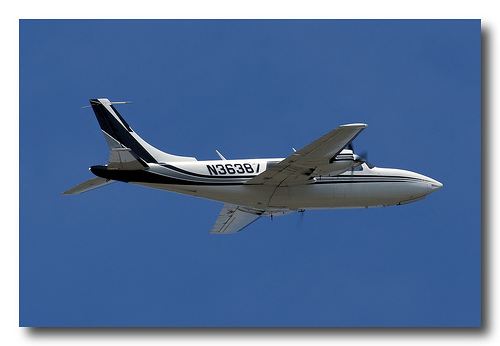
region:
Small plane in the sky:
[69, 80, 427, 255]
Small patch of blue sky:
[39, 266, 118, 342]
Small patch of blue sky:
[113, 261, 146, 298]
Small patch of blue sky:
[139, 255, 189, 312]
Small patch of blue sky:
[176, 250, 215, 300]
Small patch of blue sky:
[222, 246, 264, 290]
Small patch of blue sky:
[258, 258, 305, 315]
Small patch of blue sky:
[300, 266, 343, 316]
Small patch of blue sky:
[336, 268, 382, 305]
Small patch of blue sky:
[395, 243, 438, 302]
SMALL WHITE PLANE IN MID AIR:
[74, 84, 496, 264]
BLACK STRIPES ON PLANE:
[205, 173, 432, 187]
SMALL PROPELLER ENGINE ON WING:
[288, 145, 363, 173]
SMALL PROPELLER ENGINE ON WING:
[234, 202, 311, 222]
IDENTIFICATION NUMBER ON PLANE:
[187, 141, 272, 184]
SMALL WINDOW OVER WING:
[257, 153, 289, 166]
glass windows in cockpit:
[340, 142, 390, 183]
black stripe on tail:
[76, 78, 175, 195]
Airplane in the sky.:
[51, 85, 446, 247]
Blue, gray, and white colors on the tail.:
[85, 90, 190, 160]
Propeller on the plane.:
[350, 135, 375, 170]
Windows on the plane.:
[345, 155, 375, 175]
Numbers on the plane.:
[200, 160, 255, 175]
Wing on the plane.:
[250, 110, 365, 180]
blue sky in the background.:
[15, 20, 475, 320]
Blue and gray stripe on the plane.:
[140, 155, 425, 195]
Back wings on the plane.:
[39, 139, 155, 209]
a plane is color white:
[53, 90, 450, 244]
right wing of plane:
[258, 112, 374, 188]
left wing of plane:
[210, 200, 260, 235]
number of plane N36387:
[200, 150, 265, 177]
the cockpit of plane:
[402, 161, 447, 198]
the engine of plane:
[333, 141, 378, 181]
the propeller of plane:
[349, 141, 376, 176]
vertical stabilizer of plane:
[86, 87, 176, 162]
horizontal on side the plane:
[60, 173, 111, 203]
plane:
[74, 81, 452, 236]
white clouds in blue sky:
[277, 253, 332, 293]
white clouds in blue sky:
[357, 256, 458, 323]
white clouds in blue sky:
[127, 275, 192, 320]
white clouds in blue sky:
[120, 282, 205, 339]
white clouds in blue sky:
[327, 283, 388, 310]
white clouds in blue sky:
[78, 243, 149, 285]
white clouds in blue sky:
[385, 81, 443, 116]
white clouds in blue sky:
[247, 81, 314, 112]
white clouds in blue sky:
[171, 72, 209, 102]